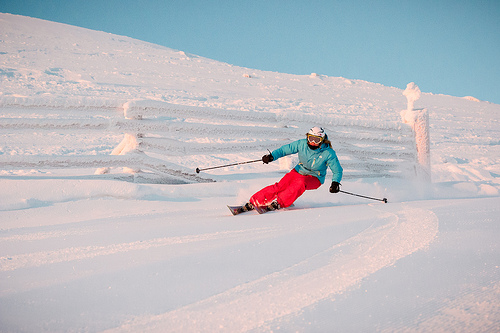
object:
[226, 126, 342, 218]
skiier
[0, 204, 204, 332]
snow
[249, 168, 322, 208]
pants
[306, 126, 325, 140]
helmet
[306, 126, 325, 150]
head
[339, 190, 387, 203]
ski pole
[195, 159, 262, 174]
ski pole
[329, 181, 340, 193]
glove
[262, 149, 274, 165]
glove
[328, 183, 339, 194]
left hand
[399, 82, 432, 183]
pole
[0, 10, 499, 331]
ground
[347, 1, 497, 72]
sky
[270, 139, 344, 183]
jacket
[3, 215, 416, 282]
tracks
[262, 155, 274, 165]
right hand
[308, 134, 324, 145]
goggles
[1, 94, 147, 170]
fence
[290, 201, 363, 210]
shadow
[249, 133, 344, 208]
snowsuit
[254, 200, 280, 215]
ski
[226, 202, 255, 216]
ski